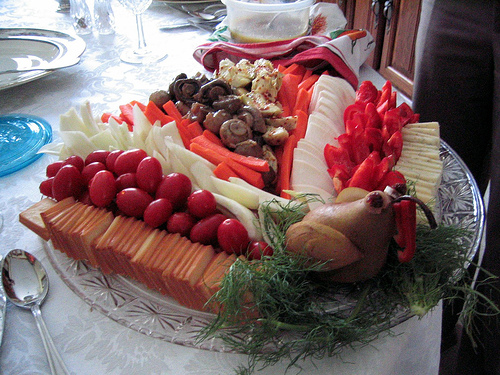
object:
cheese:
[18, 190, 80, 238]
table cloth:
[0, 0, 461, 373]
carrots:
[99, 98, 271, 191]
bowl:
[218, 0, 320, 49]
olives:
[35, 142, 275, 261]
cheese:
[197, 245, 261, 320]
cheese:
[382, 186, 448, 229]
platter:
[17, 54, 484, 364]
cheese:
[398, 121, 440, 149]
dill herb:
[383, 254, 455, 299]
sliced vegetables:
[71, 90, 284, 231]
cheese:
[95, 207, 143, 282]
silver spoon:
[0, 249, 85, 375]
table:
[0, 0, 442, 374]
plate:
[0, 27, 87, 90]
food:
[17, 57, 499, 373]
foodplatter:
[17, 56, 486, 353]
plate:
[338, 194, 455, 271]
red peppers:
[322, 77, 420, 264]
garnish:
[359, 186, 500, 358]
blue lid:
[0, 108, 55, 178]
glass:
[101, 0, 178, 67]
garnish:
[227, 262, 425, 358]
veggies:
[191, 42, 400, 190]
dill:
[196, 326, 334, 374]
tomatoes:
[30, 146, 283, 261]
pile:
[37, 146, 269, 252]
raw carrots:
[262, 58, 331, 201]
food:
[23, 30, 424, 275]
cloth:
[190, 26, 378, 92]